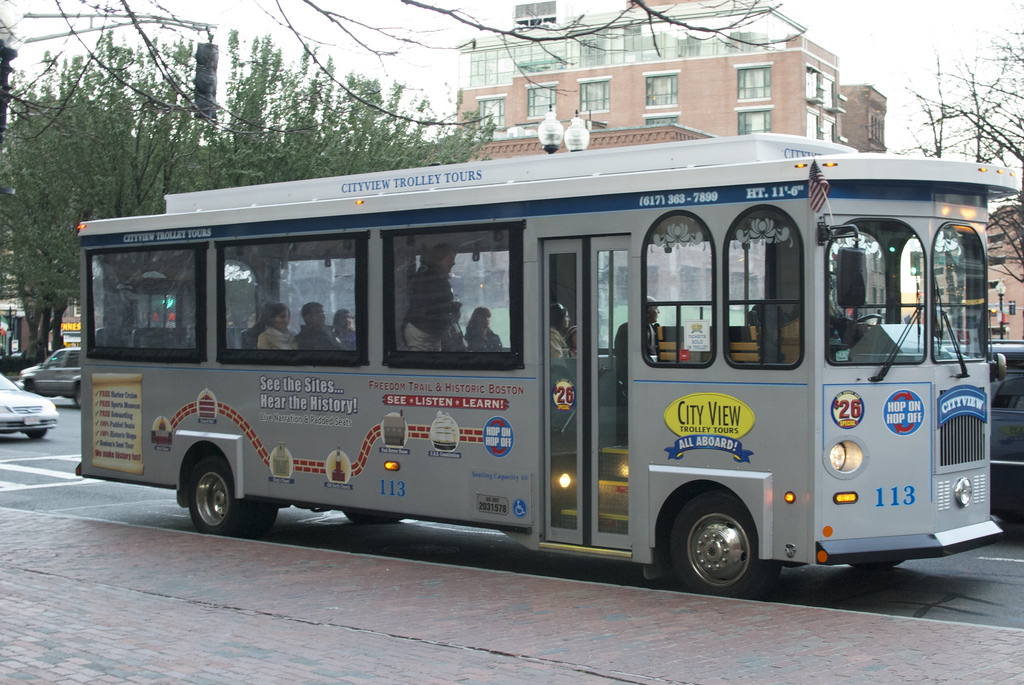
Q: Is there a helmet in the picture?
A: No, there are no helmets.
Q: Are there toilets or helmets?
A: No, there are no helmets or toilets.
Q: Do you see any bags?
A: No, there are no bags.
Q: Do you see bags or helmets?
A: No, there are no bags or helmets.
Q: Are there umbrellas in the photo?
A: No, there are no umbrellas.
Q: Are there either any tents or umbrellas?
A: No, there are no umbrellas or tents.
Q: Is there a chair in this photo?
A: No, there are no chairs.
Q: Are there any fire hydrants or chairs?
A: No, there are no chairs or fire hydrants.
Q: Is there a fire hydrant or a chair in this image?
A: No, there are no chairs or fire hydrants.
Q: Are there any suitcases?
A: No, there are no suitcases.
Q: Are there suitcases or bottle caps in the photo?
A: No, there are no suitcases or bottle caps.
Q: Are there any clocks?
A: No, there are no clocks.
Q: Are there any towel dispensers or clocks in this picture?
A: No, there are no clocks or towel dispensers.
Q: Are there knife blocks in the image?
A: No, there are no knife blocks.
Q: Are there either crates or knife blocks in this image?
A: No, there are no knife blocks or crates.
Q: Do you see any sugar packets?
A: No, there are no sugar packets.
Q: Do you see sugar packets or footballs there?
A: No, there are no sugar packets or footballs.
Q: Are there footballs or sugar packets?
A: No, there are no sugar packets or footballs.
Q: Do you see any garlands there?
A: No, there are no garlands.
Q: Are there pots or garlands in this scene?
A: No, there are no garlands or pots.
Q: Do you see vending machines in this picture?
A: No, there are no vending machines.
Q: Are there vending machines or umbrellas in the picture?
A: No, there are no vending machines or umbrellas.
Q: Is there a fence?
A: No, there are no fences.